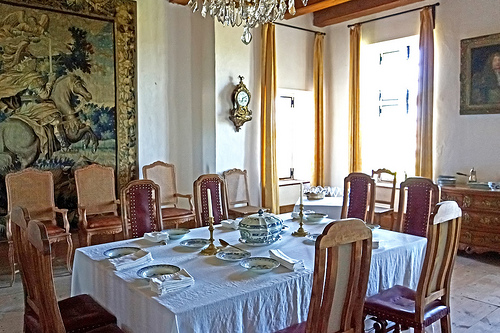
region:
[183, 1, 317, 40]
The chandelier hanging above the table.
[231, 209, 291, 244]
The silver pot in the middle of the table.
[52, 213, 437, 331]
The white table cloth on the center table.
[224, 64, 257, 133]
The gold clock on the wall.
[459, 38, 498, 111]
The art frame on the right wall.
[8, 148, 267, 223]
The wood chairs against the wall.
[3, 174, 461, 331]
The chairs surrounding the center table.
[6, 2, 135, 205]
The large art piece on the wall behind the chairs.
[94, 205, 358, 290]
The dishes and plates on the center table.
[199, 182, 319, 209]
The candles on the center table.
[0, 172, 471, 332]
a dining table with seven chairs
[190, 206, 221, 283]
a brass candle holder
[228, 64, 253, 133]
a clock hanging on a wall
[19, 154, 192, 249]
three chairs against a wall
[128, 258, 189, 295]
a blue and white bowl on a table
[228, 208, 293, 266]
a blue and white soup bowl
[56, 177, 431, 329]
a table with a white table cloth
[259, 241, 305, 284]
a white napkin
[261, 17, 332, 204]
yellow curtains covering a window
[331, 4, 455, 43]
a dark colored curtain rod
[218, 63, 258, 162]
the clock on the wall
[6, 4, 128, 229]
a large painting hanging on the wall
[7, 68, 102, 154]
there is a horse in the large painting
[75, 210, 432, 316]
this is a dining table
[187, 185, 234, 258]
a candle is on the table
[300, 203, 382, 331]
the back of a chair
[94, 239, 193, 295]
two plates sitting on the table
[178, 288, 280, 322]
the tablecloth is white in color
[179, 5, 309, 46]
a portion of the chandelier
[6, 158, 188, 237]
three chairs up against the wall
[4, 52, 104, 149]
A knight riding a horse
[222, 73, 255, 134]
A clock hanging from the wall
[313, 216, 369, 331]
A wooden dining chair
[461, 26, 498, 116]
A portrait hanging from the wall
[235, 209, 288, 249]
A silver tray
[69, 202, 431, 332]
A dining table with dining ware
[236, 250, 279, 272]
A plate sitting on the table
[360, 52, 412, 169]
Sun shining through a window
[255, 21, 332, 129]
Tan window curtains drawn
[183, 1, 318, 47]
A glass chandelier hanging from the ceiling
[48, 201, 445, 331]
white tablecloth on rectangular table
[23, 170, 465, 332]
wooden chairs surrounding table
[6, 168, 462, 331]
wooden chairs with red cushions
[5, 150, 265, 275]
wooden chairs against wall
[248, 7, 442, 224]
gold curtains surround windows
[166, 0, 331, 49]
chandelier hanging over table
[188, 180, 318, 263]
two candles on table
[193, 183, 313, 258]
white candles in brass holders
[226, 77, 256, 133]
brass clock with white face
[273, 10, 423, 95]
window shades partially drawn